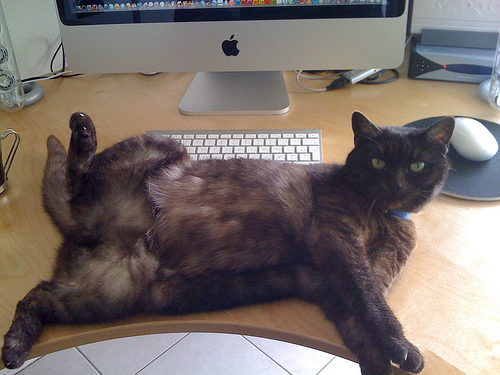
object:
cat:
[0, 111, 456, 375]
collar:
[376, 208, 412, 219]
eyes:
[370, 157, 426, 174]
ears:
[351, 109, 455, 147]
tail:
[39, 133, 74, 232]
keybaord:
[144, 128, 323, 166]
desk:
[429, 221, 500, 375]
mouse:
[450, 117, 499, 161]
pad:
[400, 115, 500, 201]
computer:
[53, 0, 412, 116]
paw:
[386, 343, 425, 374]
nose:
[384, 179, 403, 191]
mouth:
[375, 185, 410, 208]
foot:
[65, 110, 97, 198]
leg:
[15, 276, 104, 330]